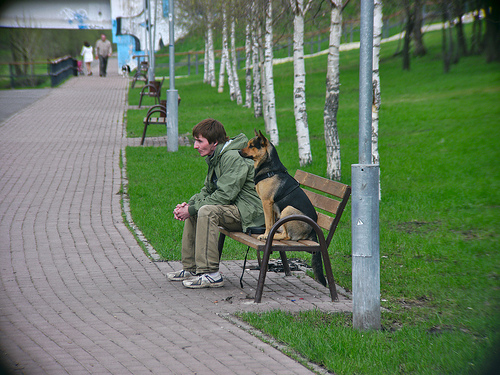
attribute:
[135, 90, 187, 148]
bench — brown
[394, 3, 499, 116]
trees — white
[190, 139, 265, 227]
jacket — green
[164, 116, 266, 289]
man — sitting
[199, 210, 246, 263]
pants — brown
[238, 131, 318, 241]
dog — sitting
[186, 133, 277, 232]
coat — green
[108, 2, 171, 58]
building — white, blue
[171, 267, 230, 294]
sneakers — white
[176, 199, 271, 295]
pants — brown